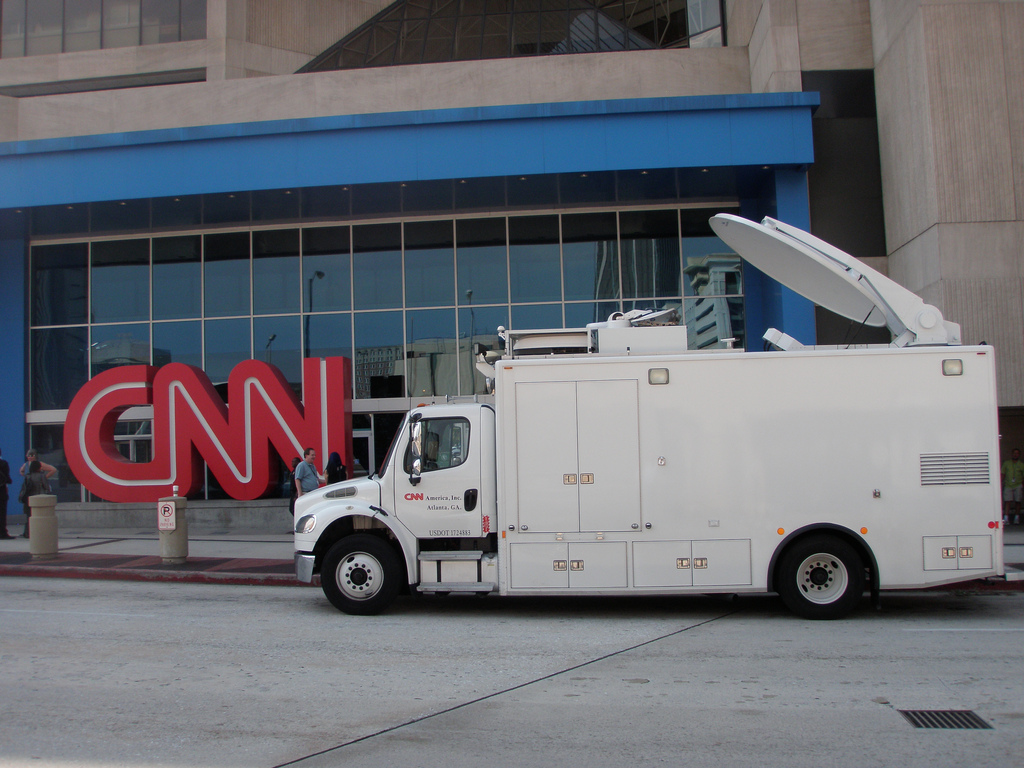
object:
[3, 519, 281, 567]
pavement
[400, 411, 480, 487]
window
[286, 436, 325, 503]
man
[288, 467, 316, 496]
shirt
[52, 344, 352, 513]
sign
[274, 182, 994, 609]
truck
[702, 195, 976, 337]
dish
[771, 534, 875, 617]
tire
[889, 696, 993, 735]
grate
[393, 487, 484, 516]
sticker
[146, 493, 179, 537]
sign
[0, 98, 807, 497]
area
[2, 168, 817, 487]
entrance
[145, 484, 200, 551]
post